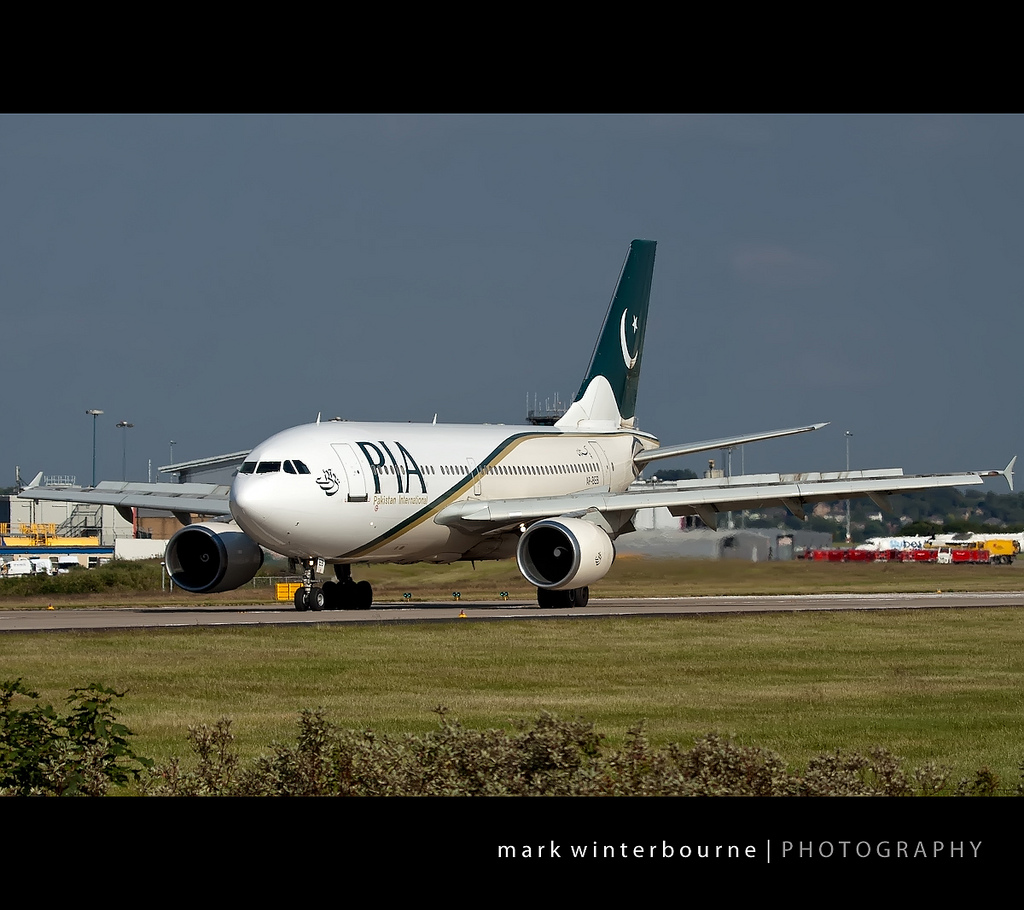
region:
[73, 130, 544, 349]
the sky is grey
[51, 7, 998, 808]
the sky is grey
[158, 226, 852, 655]
A large plane is white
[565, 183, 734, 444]
The plane's tail is mostly dark green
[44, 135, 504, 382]
The sky is blue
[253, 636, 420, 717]
The grass is green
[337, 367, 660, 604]
Green and yellow stripes are on the airplane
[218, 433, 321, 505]
Windows on the airplane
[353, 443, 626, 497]
Passenger windows on a plane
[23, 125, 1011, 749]
The day appears overcast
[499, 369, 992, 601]
Wings on an airplane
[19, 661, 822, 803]
Green bushes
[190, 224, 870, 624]
passenger airplane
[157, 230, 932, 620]
airplane on run way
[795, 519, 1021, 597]
red baggage carriers in background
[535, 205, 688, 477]
crescent moon and star symbol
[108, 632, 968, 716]
green grassy field next to runway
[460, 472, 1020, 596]
airplane wing with large engine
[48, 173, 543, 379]
clear blue sky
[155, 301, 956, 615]
passenger airplane preparing for take off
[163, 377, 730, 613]
large passenger airplane with PIA on side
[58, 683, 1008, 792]
bushes in fore ground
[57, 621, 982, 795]
shrubs edging a grassy field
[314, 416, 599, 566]
slanted stripe painted on airplane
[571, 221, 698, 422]
star and arc on tail of airplane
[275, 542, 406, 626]
landing gear on bottom of plane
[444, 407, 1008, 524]
large and small wings on side of plane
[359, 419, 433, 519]
three letters of the alphabet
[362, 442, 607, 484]
long row of passenger windows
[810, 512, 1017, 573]
airport trucks for support and maintenance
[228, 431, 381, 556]
door near nose of airplane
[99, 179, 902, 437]
dark grey sky over runway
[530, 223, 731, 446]
plane's tail has moon and star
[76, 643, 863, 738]
the grass are green and brown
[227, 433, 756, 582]
the plane is white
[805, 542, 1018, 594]
the cargo containers are red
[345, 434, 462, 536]
PIA is on plane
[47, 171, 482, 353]
the sky is gray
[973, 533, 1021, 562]
the truck is yellow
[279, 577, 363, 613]
the wheels are black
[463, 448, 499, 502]
the door is closed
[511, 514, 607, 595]
the air vent lining is silver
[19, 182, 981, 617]
PIA jet on runway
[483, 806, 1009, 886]
name of photographer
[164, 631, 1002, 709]
patch of grass near runway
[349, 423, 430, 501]
PIA written on side of plane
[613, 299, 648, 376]
airline logo on rear of plane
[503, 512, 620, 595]
plane's left engine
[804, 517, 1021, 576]
row of service vehicles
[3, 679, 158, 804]
patch of shrubbery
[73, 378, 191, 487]
section of light poles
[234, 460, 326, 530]
nose of airplane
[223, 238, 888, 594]
Jet Airplane on runway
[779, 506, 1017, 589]
Airport vehicles at an airport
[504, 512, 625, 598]
Jet engine on a passenger plane.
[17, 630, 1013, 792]
grass and plants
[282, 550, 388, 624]
Airplane wheels on an jet airplane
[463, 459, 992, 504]
Airplane wing of a jet plane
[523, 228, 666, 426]
Tail of an airplane on the runway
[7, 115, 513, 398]
blue sky over the airport